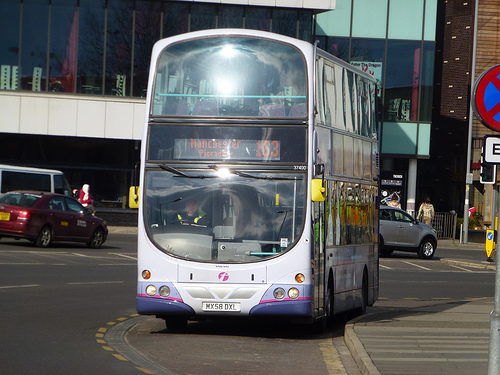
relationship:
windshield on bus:
[140, 160, 311, 263] [100, 10, 442, 357]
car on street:
[376, 204, 439, 258] [0, 230, 500, 372]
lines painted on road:
[1, 247, 133, 291] [1, 222, 498, 373]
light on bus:
[145, 283, 157, 297] [134, 25, 384, 329]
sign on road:
[473, 65, 498, 166] [0, 247, 499, 372]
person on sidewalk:
[416, 197, 436, 224] [438, 237, 497, 250]